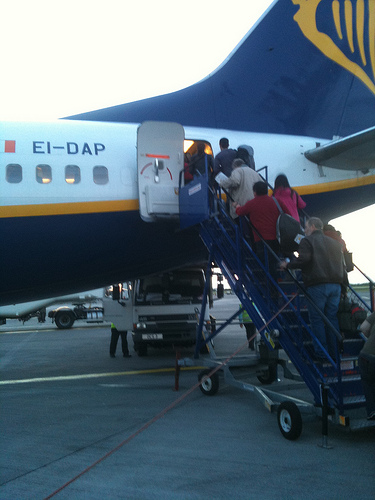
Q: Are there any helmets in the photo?
A: No, there are no helmets.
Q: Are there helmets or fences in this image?
A: No, there are no helmets or fences.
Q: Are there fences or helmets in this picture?
A: No, there are no helmets or fences.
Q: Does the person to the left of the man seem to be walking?
A: Yes, the person is walking.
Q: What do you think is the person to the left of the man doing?
A: The person is walking.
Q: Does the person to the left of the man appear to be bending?
A: No, the person is walking.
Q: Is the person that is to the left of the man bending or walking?
A: The person is walking.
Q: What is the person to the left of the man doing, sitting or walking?
A: The person is walking.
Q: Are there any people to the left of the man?
A: Yes, there is a person to the left of the man.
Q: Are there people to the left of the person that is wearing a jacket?
A: Yes, there is a person to the left of the man.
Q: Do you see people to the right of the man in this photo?
A: No, the person is to the left of the man.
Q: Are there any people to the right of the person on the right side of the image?
A: No, the person is to the left of the man.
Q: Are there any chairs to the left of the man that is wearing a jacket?
A: No, there is a person to the left of the man.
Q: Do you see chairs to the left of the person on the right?
A: No, there is a person to the left of the man.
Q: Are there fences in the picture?
A: No, there are no fences.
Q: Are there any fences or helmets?
A: No, there are no fences or helmets.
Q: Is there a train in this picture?
A: No, there are no trains.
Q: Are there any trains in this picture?
A: No, there are no trains.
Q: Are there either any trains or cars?
A: No, there are no trains or cars.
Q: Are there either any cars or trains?
A: No, there are no trains or cars.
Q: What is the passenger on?
A: The passenger is on the stairs.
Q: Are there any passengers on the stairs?
A: Yes, there is a passenger on the stairs.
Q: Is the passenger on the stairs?
A: Yes, the passenger is on the stairs.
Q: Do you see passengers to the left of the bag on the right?
A: Yes, there is a passenger to the left of the bag.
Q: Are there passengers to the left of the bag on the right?
A: Yes, there is a passenger to the left of the bag.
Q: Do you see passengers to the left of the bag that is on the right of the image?
A: Yes, there is a passenger to the left of the bag.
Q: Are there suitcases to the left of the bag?
A: No, there is a passenger to the left of the bag.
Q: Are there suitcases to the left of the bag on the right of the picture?
A: No, there is a passenger to the left of the bag.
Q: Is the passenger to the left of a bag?
A: Yes, the passenger is to the left of a bag.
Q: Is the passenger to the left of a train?
A: No, the passenger is to the left of a bag.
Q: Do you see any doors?
A: Yes, there is a door.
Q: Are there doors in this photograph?
A: Yes, there is a door.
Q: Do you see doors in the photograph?
A: Yes, there is a door.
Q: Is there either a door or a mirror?
A: Yes, there is a door.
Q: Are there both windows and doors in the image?
A: Yes, there are both a door and windows.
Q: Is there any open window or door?
A: Yes, there is an open door.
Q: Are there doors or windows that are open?
A: Yes, the door is open.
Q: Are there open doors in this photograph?
A: Yes, there is an open door.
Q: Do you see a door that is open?
A: Yes, there is a door that is open.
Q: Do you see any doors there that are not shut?
A: Yes, there is a open door.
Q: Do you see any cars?
A: No, there are no cars.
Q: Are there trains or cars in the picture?
A: No, there are no cars or trains.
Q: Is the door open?
A: Yes, the door is open.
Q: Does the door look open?
A: Yes, the door is open.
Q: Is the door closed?
A: No, the door is open.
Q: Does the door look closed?
A: No, the door is open.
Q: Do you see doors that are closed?
A: No, there is a door but it is open.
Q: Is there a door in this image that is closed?
A: No, there is a door but it is open.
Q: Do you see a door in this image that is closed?
A: No, there is a door but it is open.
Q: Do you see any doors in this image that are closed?
A: No, there is a door but it is open.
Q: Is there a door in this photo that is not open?
A: No, there is a door but it is open.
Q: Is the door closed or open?
A: The door is open.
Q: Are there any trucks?
A: Yes, there is a truck.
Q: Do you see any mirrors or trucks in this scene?
A: Yes, there is a truck.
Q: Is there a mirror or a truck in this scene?
A: Yes, there is a truck.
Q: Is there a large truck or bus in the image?
A: Yes, there is a large truck.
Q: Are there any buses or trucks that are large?
A: Yes, the truck is large.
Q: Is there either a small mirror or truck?
A: Yes, there is a small truck.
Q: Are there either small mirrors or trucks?
A: Yes, there is a small truck.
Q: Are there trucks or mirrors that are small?
A: Yes, the truck is small.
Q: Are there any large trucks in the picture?
A: Yes, there is a large truck.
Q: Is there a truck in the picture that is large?
A: Yes, there is a truck that is large.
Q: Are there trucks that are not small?
A: Yes, there is a large truck.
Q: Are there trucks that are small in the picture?
A: Yes, there is a small truck.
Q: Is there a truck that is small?
A: Yes, there is a truck that is small.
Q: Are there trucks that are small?
A: Yes, there is a truck that is small.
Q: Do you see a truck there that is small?
A: Yes, there is a truck that is small.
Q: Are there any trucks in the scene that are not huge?
A: Yes, there is a small truck.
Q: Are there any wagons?
A: No, there are no wagons.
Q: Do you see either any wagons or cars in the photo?
A: No, there are no wagons or cars.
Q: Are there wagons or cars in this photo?
A: No, there are no wagons or cars.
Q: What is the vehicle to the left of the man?
A: The vehicle is a truck.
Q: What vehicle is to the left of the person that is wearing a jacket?
A: The vehicle is a truck.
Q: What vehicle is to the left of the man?
A: The vehicle is a truck.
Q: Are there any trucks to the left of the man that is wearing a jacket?
A: Yes, there is a truck to the left of the man.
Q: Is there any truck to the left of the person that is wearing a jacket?
A: Yes, there is a truck to the left of the man.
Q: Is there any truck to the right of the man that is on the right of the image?
A: No, the truck is to the left of the man.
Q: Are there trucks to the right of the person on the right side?
A: No, the truck is to the left of the man.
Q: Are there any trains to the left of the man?
A: No, there is a truck to the left of the man.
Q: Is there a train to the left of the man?
A: No, there is a truck to the left of the man.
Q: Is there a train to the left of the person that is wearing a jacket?
A: No, there is a truck to the left of the man.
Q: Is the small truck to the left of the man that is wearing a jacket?
A: Yes, the truck is to the left of the man.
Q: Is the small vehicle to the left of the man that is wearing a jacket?
A: Yes, the truck is to the left of the man.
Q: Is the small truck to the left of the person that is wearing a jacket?
A: Yes, the truck is to the left of the man.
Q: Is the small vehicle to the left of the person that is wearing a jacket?
A: Yes, the truck is to the left of the man.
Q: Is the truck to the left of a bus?
A: No, the truck is to the left of the man.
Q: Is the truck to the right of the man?
A: No, the truck is to the left of the man.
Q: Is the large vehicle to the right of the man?
A: No, the truck is to the left of the man.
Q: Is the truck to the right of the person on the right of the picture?
A: No, the truck is to the left of the man.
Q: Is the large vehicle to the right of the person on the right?
A: No, the truck is to the left of the man.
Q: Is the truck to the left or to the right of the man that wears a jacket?
A: The truck is to the left of the man.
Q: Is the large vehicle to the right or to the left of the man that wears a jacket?
A: The truck is to the left of the man.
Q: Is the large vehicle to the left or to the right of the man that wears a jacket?
A: The truck is to the left of the man.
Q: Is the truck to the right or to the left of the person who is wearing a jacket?
A: The truck is to the left of the man.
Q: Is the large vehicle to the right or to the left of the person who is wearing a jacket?
A: The truck is to the left of the man.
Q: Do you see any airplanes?
A: Yes, there is an airplane.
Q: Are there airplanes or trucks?
A: Yes, there is an airplane.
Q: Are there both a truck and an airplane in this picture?
A: Yes, there are both an airplane and a truck.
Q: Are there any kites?
A: No, there are no kites.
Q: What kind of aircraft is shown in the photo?
A: The aircraft is an airplane.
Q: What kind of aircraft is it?
A: The aircraft is an airplane.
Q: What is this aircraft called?
A: This is an airplane.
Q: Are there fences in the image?
A: No, there are no fences.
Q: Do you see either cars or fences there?
A: No, there are no fences or cars.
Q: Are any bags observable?
A: Yes, there is a bag.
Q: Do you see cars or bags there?
A: Yes, there is a bag.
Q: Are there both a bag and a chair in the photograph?
A: No, there is a bag but no chairs.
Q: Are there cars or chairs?
A: No, there are no cars or chairs.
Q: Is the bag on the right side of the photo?
A: Yes, the bag is on the right of the image.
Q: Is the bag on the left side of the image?
A: No, the bag is on the right of the image.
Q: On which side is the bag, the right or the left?
A: The bag is on the right of the image.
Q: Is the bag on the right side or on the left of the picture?
A: The bag is on the right of the image.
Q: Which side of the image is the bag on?
A: The bag is on the right of the image.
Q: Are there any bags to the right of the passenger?
A: Yes, there is a bag to the right of the passenger.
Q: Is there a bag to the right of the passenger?
A: Yes, there is a bag to the right of the passenger.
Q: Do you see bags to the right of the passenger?
A: Yes, there is a bag to the right of the passenger.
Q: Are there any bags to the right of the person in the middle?
A: Yes, there is a bag to the right of the passenger.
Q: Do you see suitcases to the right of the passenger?
A: No, there is a bag to the right of the passenger.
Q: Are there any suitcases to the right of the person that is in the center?
A: No, there is a bag to the right of the passenger.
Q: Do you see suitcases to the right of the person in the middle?
A: No, there is a bag to the right of the passenger.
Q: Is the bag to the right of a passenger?
A: Yes, the bag is to the right of a passenger.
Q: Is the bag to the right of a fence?
A: No, the bag is to the right of a passenger.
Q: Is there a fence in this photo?
A: No, there are no fences.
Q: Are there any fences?
A: No, there are no fences.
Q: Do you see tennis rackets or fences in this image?
A: No, there are no fences or tennis rackets.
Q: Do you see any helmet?
A: No, there are no helmets.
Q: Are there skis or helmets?
A: No, there are no helmets or skis.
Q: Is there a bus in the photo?
A: No, there are no buses.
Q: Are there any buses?
A: No, there are no buses.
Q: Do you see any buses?
A: No, there are no buses.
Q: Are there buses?
A: No, there are no buses.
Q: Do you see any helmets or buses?
A: No, there are no buses or helmets.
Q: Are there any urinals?
A: No, there are no urinals.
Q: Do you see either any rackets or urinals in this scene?
A: No, there are no urinals or rackets.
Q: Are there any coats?
A: Yes, there is a coat.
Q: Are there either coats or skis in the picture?
A: Yes, there is a coat.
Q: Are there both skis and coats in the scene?
A: No, there is a coat but no skis.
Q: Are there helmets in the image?
A: No, there are no helmets.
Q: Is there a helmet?
A: No, there are no helmets.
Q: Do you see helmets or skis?
A: No, there are no helmets or skis.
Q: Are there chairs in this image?
A: No, there are no chairs.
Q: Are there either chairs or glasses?
A: No, there are no chairs or glasses.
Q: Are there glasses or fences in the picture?
A: No, there are no fences or glasses.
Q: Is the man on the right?
A: Yes, the man is on the right of the image.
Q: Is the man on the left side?
A: No, the man is on the right of the image.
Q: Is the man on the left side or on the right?
A: The man is on the right of the image.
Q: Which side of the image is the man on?
A: The man is on the right of the image.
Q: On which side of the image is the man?
A: The man is on the right of the image.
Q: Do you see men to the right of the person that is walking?
A: Yes, there is a man to the right of the person.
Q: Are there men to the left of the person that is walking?
A: No, the man is to the right of the person.